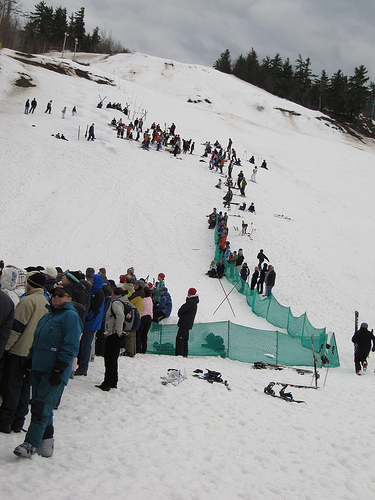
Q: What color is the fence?
A: Green.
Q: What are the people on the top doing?
A: Skiing.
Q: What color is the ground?
A: White.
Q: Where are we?
A: At a ski resort.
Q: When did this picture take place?
A: During the day.